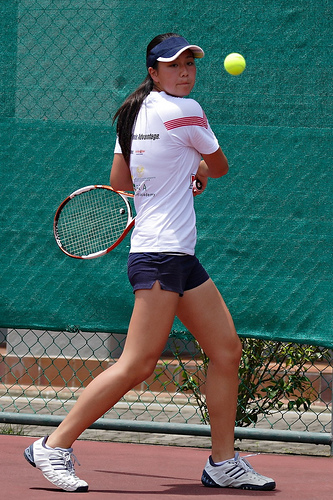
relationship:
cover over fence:
[0, 1, 332, 348] [2, 4, 331, 444]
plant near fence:
[161, 331, 323, 449] [2, 4, 331, 444]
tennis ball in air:
[224, 52, 246, 77] [0, 2, 332, 384]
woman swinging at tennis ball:
[24, 33, 276, 491] [224, 52, 246, 77]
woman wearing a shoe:
[24, 33, 276, 491] [23, 435, 89, 493]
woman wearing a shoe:
[24, 33, 276, 491] [199, 454, 276, 492]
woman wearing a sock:
[24, 33, 276, 491] [43, 443, 53, 451]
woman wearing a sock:
[24, 33, 276, 491] [216, 458, 234, 467]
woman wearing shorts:
[24, 33, 276, 491] [127, 252, 211, 297]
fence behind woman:
[2, 4, 331, 444] [24, 33, 276, 491]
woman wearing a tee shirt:
[24, 33, 276, 491] [113, 91, 221, 255]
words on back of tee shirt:
[131, 132, 160, 143] [113, 91, 221, 255]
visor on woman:
[147, 37, 205, 63] [24, 33, 276, 491]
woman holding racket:
[24, 33, 276, 491] [52, 183, 138, 261]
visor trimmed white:
[147, 37, 205, 63] [156, 45, 203, 63]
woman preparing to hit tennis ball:
[24, 33, 276, 491] [224, 52, 246, 77]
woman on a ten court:
[24, 33, 276, 491] [2, 435, 332, 499]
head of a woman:
[145, 33, 197, 97] [24, 33, 276, 491]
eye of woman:
[168, 62, 179, 69] [24, 33, 276, 491]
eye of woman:
[186, 61, 195, 67] [24, 33, 276, 491]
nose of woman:
[181, 62, 190, 78] [24, 33, 276, 491]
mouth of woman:
[177, 81, 191, 87] [24, 33, 276, 491]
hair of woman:
[112, 32, 184, 161] [24, 33, 276, 491]